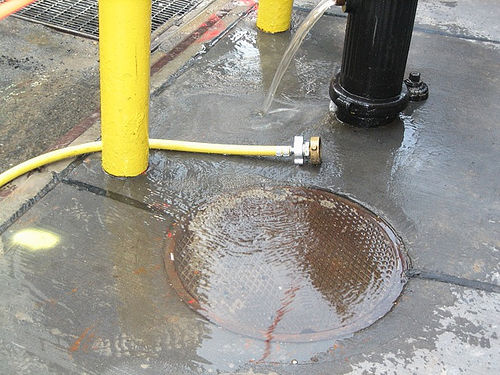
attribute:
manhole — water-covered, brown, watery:
[157, 188, 449, 355]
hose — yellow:
[0, 123, 321, 207]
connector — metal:
[275, 138, 325, 177]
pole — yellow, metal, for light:
[88, 4, 153, 198]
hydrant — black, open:
[321, 6, 417, 113]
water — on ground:
[258, 1, 338, 116]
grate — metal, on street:
[5, 2, 197, 72]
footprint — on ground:
[97, 313, 216, 367]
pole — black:
[301, 4, 409, 150]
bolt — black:
[401, 67, 425, 102]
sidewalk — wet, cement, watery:
[15, 1, 487, 363]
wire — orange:
[0, 1, 34, 22]